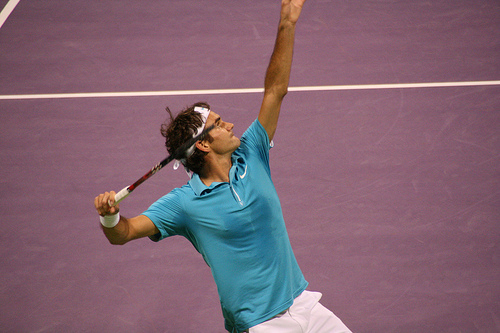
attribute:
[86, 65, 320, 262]
man — serving, concentrating, holding, looking, wearing, playing, swinging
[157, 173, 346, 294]
shirt — blue, wet, polo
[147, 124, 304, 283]
polo — blue, green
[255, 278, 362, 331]
shorts — white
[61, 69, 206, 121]
line — white, painted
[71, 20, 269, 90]
court — purple, large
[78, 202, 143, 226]
wristband — white, soft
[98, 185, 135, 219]
hand — clenched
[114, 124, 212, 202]
racket — tennis, white, held, handled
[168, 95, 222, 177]
headband — white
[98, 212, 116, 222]
band — white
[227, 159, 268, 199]
logo — nike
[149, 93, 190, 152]
hair — brown, short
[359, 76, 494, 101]
stripe — white